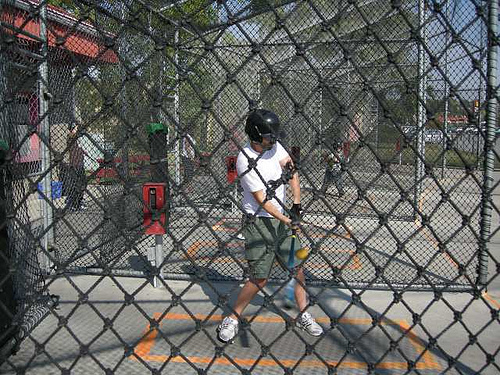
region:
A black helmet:
[242, 107, 282, 134]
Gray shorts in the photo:
[235, 220, 302, 280]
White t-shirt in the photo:
[231, 144, 297, 220]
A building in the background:
[27, 35, 96, 137]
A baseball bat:
[286, 214, 303, 264]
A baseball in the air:
[293, 243, 315, 268]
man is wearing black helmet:
[239, 97, 290, 165]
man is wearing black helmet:
[232, 99, 289, 157]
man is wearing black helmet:
[236, 97, 300, 164]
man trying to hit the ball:
[217, 89, 332, 360]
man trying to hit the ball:
[208, 79, 327, 349]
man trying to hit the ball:
[213, 98, 323, 355]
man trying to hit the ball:
[204, 95, 327, 372]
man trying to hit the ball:
[199, 91, 344, 362]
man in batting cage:
[203, 103, 343, 357]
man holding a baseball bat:
[182, 73, 361, 358]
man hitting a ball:
[167, 83, 344, 358]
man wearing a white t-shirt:
[212, 81, 335, 358]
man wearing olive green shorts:
[188, 65, 350, 338]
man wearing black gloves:
[192, 101, 359, 343]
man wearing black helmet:
[199, 105, 347, 342]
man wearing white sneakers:
[185, 77, 357, 345]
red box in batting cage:
[136, 168, 178, 260]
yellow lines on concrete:
[123, 298, 441, 373]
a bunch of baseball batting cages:
[3, 3, 491, 358]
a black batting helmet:
[236, 103, 293, 149]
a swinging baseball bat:
[271, 196, 307, 280]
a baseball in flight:
[289, 243, 325, 264]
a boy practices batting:
[205, 103, 336, 345]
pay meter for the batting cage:
[136, 171, 191, 301]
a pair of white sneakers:
[214, 305, 331, 351]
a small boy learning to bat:
[316, 138, 353, 198]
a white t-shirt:
[224, 137, 311, 219]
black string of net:
[2, 2, 497, 370]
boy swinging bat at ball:
[215, 105, 320, 340]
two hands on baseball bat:
[280, 201, 300, 306]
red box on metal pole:
[140, 180, 165, 285]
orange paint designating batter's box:
[131, 310, 436, 366]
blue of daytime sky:
[107, 0, 492, 95]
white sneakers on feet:
[217, 310, 319, 337]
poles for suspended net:
[36, 1, 496, 287]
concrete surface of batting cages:
[9, 167, 494, 374]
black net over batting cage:
[2, 1, 497, 372]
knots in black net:
[104, 292, 160, 354]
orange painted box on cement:
[132, 312, 438, 370]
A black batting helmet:
[238, 105, 284, 143]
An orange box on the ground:
[132, 305, 444, 372]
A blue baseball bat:
[284, 209, 306, 318]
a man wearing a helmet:
[221, 90, 281, 172]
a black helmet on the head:
[258, 103, 270, 150]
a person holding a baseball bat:
[252, 106, 316, 281]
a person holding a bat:
[246, 163, 302, 339]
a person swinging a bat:
[224, 118, 296, 268]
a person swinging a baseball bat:
[233, 100, 322, 303]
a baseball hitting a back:
[293, 243, 320, 272]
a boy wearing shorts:
[231, 105, 313, 279]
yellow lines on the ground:
[136, 277, 290, 359]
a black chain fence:
[153, 89, 470, 360]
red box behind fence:
[137, 182, 173, 235]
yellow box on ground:
[133, 290, 439, 373]